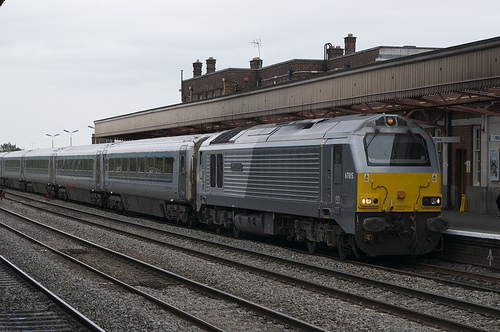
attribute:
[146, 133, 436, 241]
train — here, yellow, silver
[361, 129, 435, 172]
window — here, small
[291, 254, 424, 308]
track — under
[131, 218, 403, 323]
tracks — under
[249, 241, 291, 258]
rocks — under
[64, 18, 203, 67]
sky — here, blue, white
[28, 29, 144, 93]
clouds — white, here